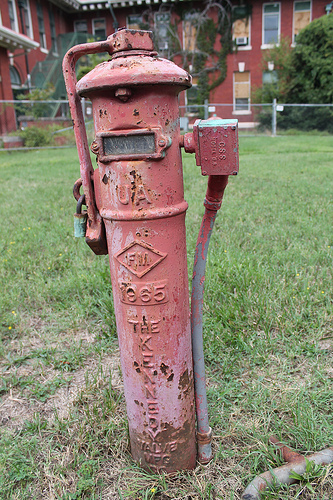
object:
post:
[270, 97, 279, 134]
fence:
[0, 99, 333, 140]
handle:
[61, 38, 112, 266]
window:
[232, 16, 251, 49]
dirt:
[0, 321, 121, 474]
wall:
[171, 0, 333, 121]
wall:
[0, 0, 70, 134]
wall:
[107, 9, 125, 33]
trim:
[261, 1, 281, 48]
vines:
[205, 65, 227, 91]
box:
[196, 119, 241, 177]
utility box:
[59, 23, 242, 478]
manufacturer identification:
[123, 314, 179, 473]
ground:
[0, 135, 332, 498]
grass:
[0, 133, 333, 496]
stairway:
[16, 30, 86, 117]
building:
[0, 1, 331, 152]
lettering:
[128, 254, 136, 268]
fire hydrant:
[60, 25, 240, 472]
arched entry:
[8, 63, 27, 133]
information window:
[102, 131, 155, 160]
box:
[98, 128, 160, 160]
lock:
[72, 194, 88, 241]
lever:
[60, 40, 109, 221]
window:
[261, 11, 282, 46]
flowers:
[7, 324, 13, 331]